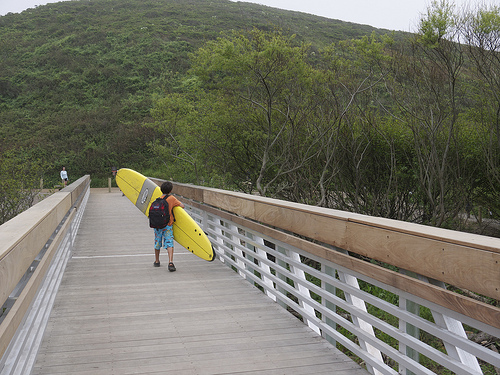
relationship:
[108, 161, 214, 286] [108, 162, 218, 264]
boy carrying surfboard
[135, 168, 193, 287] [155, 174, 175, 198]
boy with hair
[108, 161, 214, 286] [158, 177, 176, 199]
boy with hair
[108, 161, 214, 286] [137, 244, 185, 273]
boy wearing sandles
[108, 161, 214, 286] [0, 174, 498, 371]
boy walking down bridge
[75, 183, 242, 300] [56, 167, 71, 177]
person with shirt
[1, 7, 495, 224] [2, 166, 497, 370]
green trees by wooden bridge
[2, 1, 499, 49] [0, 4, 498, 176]
sky behind mountain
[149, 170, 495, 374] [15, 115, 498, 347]
railing on bridge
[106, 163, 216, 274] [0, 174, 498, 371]
boards on bridge